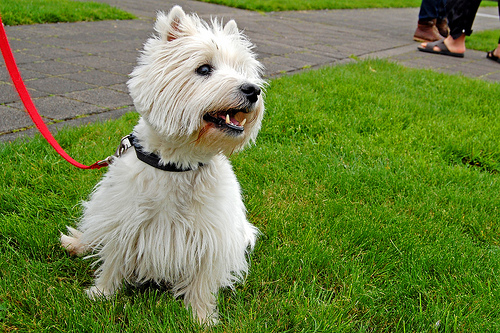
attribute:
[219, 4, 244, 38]
ear — dog's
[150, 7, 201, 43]
ear — dog's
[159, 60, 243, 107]
eye — black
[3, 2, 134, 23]
grass — short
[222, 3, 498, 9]
grass — short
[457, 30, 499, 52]
grass — short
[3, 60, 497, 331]
grass — short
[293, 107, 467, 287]
grass — green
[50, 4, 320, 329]
dog — white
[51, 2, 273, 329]
fur — white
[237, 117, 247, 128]
teeth — showing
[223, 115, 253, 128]
tooth — bottom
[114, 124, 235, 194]
collar — black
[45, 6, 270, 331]
dog — small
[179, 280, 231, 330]
paw — dog's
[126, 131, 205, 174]
collar — black, dog's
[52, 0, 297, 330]
dog — dog's, white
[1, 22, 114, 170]
leash — red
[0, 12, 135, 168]
leash — red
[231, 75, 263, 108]
nostril — dog's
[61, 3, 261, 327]
dog — white, small